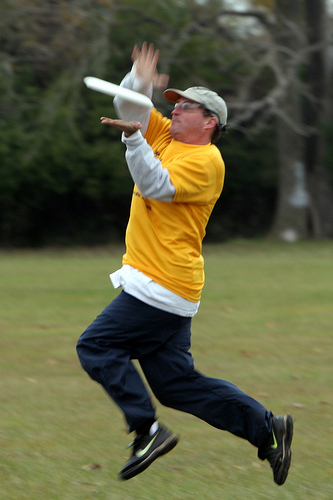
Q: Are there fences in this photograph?
A: No, there are no fences.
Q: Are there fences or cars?
A: No, there are no fences or cars.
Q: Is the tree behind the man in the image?
A: Yes, the tree is behind the man.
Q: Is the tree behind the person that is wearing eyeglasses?
A: Yes, the tree is behind the man.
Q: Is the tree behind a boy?
A: No, the tree is behind the man.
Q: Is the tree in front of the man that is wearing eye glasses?
A: No, the tree is behind the man.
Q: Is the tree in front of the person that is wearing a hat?
A: No, the tree is behind the man.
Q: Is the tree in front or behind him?
A: The tree is behind the man.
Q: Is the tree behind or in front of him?
A: The tree is behind the man.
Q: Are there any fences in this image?
A: No, there are no fences.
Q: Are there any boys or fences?
A: No, there are no fences or boys.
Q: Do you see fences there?
A: No, there are no fences.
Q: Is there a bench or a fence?
A: No, there are no fences or benches.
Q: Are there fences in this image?
A: No, there are no fences.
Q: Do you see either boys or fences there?
A: No, there are no fences or boys.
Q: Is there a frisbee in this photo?
A: Yes, there is a frisbee.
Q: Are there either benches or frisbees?
A: Yes, there is a frisbee.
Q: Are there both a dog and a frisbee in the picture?
A: No, there is a frisbee but no dogs.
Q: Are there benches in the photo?
A: No, there are no benches.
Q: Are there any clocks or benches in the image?
A: No, there are no benches or clocks.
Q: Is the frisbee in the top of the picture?
A: Yes, the frisbee is in the top of the image.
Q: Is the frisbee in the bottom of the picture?
A: No, the frisbee is in the top of the image.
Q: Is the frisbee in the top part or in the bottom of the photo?
A: The frisbee is in the top of the image.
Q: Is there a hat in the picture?
A: Yes, there is a hat.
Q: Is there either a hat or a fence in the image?
A: Yes, there is a hat.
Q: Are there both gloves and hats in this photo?
A: No, there is a hat but no gloves.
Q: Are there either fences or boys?
A: No, there are no fences or boys.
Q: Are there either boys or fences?
A: No, there are no fences or boys.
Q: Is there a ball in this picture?
A: No, there are no balls.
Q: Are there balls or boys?
A: No, there are no balls or boys.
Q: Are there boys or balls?
A: No, there are no balls or boys.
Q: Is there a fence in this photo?
A: No, there are no fences.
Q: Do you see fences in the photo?
A: No, there are no fences.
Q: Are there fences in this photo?
A: No, there are no fences.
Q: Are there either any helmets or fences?
A: No, there are no fences or helmets.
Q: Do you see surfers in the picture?
A: No, there are no surfers.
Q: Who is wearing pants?
A: The man is wearing pants.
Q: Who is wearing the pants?
A: The man is wearing pants.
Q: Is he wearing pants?
A: Yes, the man is wearing pants.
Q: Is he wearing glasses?
A: No, the man is wearing pants.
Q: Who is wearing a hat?
A: The man is wearing a hat.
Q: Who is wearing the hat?
A: The man is wearing a hat.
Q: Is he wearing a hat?
A: Yes, the man is wearing a hat.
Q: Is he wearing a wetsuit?
A: No, the man is wearing a hat.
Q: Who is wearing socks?
A: The man is wearing socks.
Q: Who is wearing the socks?
A: The man is wearing socks.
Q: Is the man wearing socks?
A: Yes, the man is wearing socks.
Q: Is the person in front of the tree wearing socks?
A: Yes, the man is wearing socks.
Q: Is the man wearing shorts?
A: No, the man is wearing socks.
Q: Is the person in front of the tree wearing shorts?
A: No, the man is wearing socks.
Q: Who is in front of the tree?
A: The man is in front of the tree.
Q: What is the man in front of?
A: The man is in front of the tree.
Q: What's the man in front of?
A: The man is in front of the tree.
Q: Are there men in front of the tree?
A: Yes, there is a man in front of the tree.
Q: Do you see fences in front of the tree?
A: No, there is a man in front of the tree.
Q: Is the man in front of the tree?
A: Yes, the man is in front of the tree.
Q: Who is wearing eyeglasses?
A: The man is wearing eyeglasses.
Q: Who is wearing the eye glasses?
A: The man is wearing eyeglasses.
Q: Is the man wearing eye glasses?
A: Yes, the man is wearing eye glasses.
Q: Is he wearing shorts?
A: No, the man is wearing eye glasses.